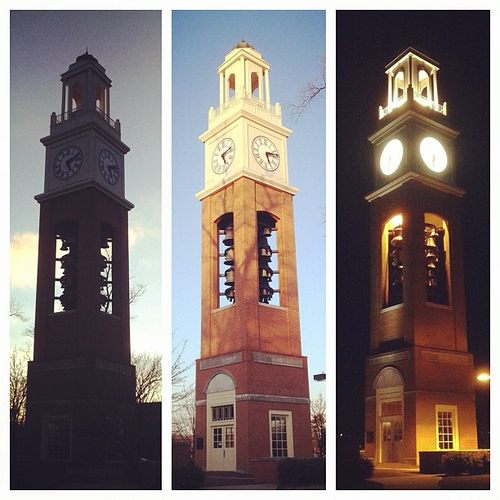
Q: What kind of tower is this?
A: Clock.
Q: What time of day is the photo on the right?
A: Night.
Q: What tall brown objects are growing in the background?
A: Trees.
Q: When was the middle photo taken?
A: 5:15.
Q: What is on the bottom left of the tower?
A: Doors.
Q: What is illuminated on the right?
A: Clock.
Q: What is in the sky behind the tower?
A: Clouds.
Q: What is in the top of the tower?
A: Clocks.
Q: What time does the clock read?
A: 5:13`.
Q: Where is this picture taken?
A: A building.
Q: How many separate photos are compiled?
A: 3.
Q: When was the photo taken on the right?
A: Night.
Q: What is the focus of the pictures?
A: Clock tower.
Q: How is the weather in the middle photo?
A: Clear.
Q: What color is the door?
A: White.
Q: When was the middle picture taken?
A: 5:15.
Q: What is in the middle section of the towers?
A: Bells.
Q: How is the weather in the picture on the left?
A: Partly cloudy.